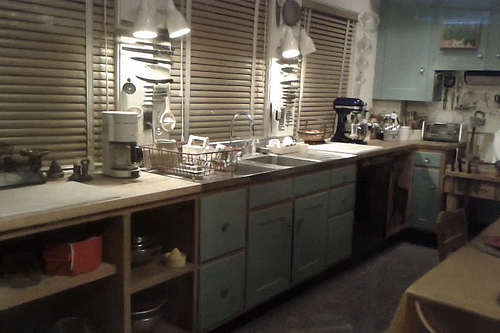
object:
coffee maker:
[100, 106, 145, 178]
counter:
[0, 167, 201, 219]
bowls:
[129, 234, 168, 332]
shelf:
[129, 199, 201, 333]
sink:
[229, 150, 350, 176]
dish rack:
[137, 141, 242, 179]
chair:
[435, 208, 468, 263]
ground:
[236, 229, 449, 332]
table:
[406, 219, 500, 323]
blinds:
[0, 0, 358, 170]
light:
[133, 0, 317, 58]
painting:
[439, 20, 481, 50]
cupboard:
[372, 1, 500, 103]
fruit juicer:
[165, 248, 187, 267]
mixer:
[331, 97, 367, 145]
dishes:
[156, 135, 227, 163]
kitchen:
[1, 1, 500, 333]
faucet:
[230, 111, 256, 148]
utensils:
[442, 74, 500, 114]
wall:
[371, 75, 500, 166]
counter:
[307, 137, 467, 155]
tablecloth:
[386, 222, 500, 333]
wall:
[0, 2, 425, 179]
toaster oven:
[421, 120, 468, 143]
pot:
[44, 235, 103, 276]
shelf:
[1, 209, 127, 333]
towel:
[392, 151, 415, 190]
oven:
[352, 160, 396, 258]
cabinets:
[197, 166, 357, 333]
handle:
[288, 221, 301, 232]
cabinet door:
[291, 192, 331, 288]